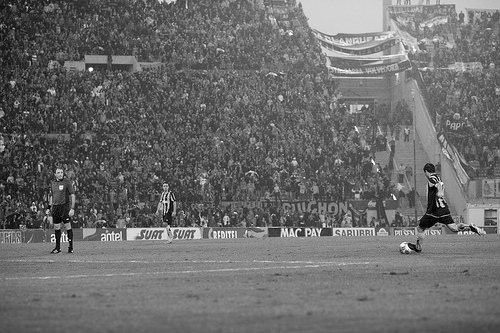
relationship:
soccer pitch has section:
[0, 227, 497, 330] [0, 229, 491, 276]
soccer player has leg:
[410, 143, 481, 251] [409, 215, 434, 253]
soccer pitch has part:
[0, 227, 497, 330] [0, 229, 491, 276]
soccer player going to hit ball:
[410, 143, 481, 251] [398, 240, 414, 256]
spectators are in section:
[389, 3, 500, 179] [386, 2, 500, 182]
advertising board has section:
[0, 224, 443, 246] [267, 227, 333, 238]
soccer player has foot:
[410, 143, 481, 251] [465, 224, 483, 235]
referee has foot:
[47, 165, 80, 255] [51, 244, 62, 258]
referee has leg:
[47, 165, 80, 255] [66, 224, 74, 253]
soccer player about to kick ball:
[410, 143, 481, 251] [398, 240, 414, 256]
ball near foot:
[398, 240, 414, 256] [409, 241, 423, 256]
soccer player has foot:
[410, 143, 481, 251] [409, 241, 423, 256]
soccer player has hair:
[410, 143, 481, 251] [421, 163, 439, 174]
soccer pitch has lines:
[0, 227, 497, 330] [0, 254, 375, 283]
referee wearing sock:
[47, 165, 80, 255] [66, 230, 74, 255]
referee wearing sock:
[47, 165, 80, 255] [53, 227, 64, 254]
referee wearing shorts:
[47, 165, 80, 255] [50, 203, 72, 227]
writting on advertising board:
[136, 230, 196, 240] [0, 224, 443, 246]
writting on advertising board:
[212, 230, 239, 241] [0, 224, 443, 246]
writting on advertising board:
[267, 227, 333, 238] [0, 224, 443, 246]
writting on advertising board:
[44, 228, 126, 248] [0, 224, 443, 246]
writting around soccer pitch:
[136, 230, 196, 240] [0, 227, 497, 330]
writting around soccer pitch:
[212, 230, 239, 241] [0, 227, 497, 330]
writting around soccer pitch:
[44, 228, 126, 248] [0, 227, 497, 330]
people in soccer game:
[114, 68, 125, 79] [4, 163, 499, 331]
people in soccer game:
[135, 105, 147, 117] [4, 163, 499, 331]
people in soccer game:
[162, 71, 172, 83] [4, 163, 499, 331]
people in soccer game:
[171, 98, 182, 105] [4, 163, 499, 331]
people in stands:
[114, 68, 125, 79] [0, 1, 379, 225]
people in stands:
[162, 71, 172, 83] [0, 1, 379, 225]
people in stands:
[135, 105, 147, 117] [0, 1, 379, 225]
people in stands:
[171, 98, 182, 105] [0, 1, 379, 225]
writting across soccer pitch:
[136, 230, 196, 240] [0, 227, 497, 330]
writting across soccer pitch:
[212, 230, 239, 241] [0, 227, 497, 330]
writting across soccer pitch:
[44, 228, 126, 248] [0, 227, 497, 330]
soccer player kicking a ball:
[410, 143, 481, 251] [398, 240, 414, 256]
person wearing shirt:
[152, 181, 177, 244] [158, 189, 180, 218]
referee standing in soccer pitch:
[47, 165, 80, 255] [0, 227, 497, 330]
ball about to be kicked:
[398, 240, 414, 256] [398, 217, 486, 255]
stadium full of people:
[0, 2, 497, 331] [162, 71, 172, 83]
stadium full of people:
[0, 2, 497, 331] [171, 98, 182, 105]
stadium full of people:
[0, 2, 497, 331] [114, 68, 125, 79]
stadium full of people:
[0, 2, 497, 331] [135, 105, 147, 117]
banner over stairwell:
[315, 27, 398, 46] [358, 126, 421, 229]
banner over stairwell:
[323, 53, 415, 79] [358, 126, 421, 229]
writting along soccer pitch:
[136, 230, 196, 240] [0, 227, 497, 330]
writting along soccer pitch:
[212, 230, 239, 241] [0, 227, 497, 330]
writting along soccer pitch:
[44, 228, 126, 248] [0, 227, 497, 330]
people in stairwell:
[404, 124, 415, 144] [358, 126, 421, 229]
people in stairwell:
[389, 136, 398, 158] [358, 126, 421, 229]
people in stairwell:
[396, 160, 409, 185] [358, 126, 421, 229]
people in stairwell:
[405, 186, 419, 212] [358, 126, 421, 229]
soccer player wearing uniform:
[410, 143, 481, 251] [418, 175, 451, 228]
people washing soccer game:
[114, 68, 125, 79] [4, 163, 499, 331]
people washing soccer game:
[162, 71, 172, 83] [4, 163, 499, 331]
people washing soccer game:
[135, 105, 147, 117] [4, 163, 499, 331]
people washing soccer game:
[171, 98, 182, 105] [4, 163, 499, 331]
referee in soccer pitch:
[47, 165, 80, 255] [0, 227, 497, 330]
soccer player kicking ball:
[410, 143, 481, 251] [398, 240, 414, 256]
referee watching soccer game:
[47, 165, 80, 255] [4, 163, 499, 331]